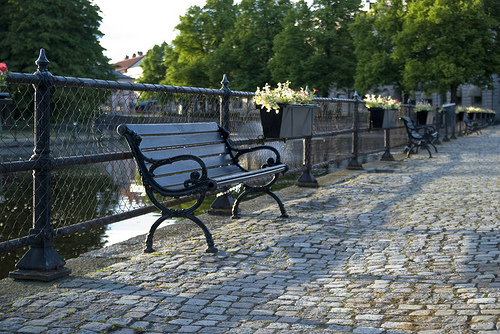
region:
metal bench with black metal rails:
[117, 120, 287, 252]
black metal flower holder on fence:
[250, 80, 318, 137]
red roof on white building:
[113, 53, 143, 70]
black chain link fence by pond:
[57, 85, 115, 212]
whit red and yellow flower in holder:
[257, 79, 317, 108]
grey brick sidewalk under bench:
[216, 212, 288, 254]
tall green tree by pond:
[401, 4, 489, 95]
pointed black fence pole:
[31, 47, 53, 266]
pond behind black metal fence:
[55, 143, 94, 235]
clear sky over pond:
[110, 3, 175, 41]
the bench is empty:
[108, 118, 286, 238]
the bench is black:
[99, 103, 294, 225]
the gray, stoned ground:
[236, 205, 368, 326]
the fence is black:
[22, 47, 117, 205]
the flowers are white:
[232, 73, 333, 130]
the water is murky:
[36, 162, 136, 249]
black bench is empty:
[119, 88, 277, 257]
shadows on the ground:
[208, 226, 356, 325]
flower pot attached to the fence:
[246, 65, 360, 162]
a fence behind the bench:
[91, 95, 423, 272]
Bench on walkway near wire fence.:
[111, 113, 291, 258]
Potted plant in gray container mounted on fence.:
[245, 75, 307, 138]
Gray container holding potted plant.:
[275, 101, 316, 137]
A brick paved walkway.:
[254, 248, 477, 331]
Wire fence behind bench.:
[56, 63, 116, 238]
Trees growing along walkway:
[360, 0, 499, 97]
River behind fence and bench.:
[56, 152, 130, 234]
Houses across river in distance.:
[110, 54, 154, 113]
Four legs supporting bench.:
[142, 190, 299, 257]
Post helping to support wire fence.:
[8, 45, 69, 283]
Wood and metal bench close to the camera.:
[113, 123, 289, 251]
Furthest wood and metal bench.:
[461, 112, 480, 134]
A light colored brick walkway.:
[4, 125, 499, 332]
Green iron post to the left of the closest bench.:
[11, 48, 73, 283]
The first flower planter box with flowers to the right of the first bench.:
[251, 79, 316, 136]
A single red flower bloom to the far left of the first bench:
[0, 60, 7, 74]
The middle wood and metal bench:
[402, 115, 439, 157]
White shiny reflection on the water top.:
[105, 192, 177, 247]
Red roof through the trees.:
[106, 56, 144, 71]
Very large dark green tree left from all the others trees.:
[0, 0, 113, 121]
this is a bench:
[132, 119, 264, 234]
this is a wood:
[146, 132, 208, 148]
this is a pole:
[27, 59, 73, 269]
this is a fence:
[61, 87, 98, 210]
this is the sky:
[114, 0, 153, 40]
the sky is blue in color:
[108, 16, 148, 37]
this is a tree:
[34, 10, 67, 42]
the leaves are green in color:
[268, 31, 298, 70]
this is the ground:
[341, 202, 421, 309]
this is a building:
[118, 55, 147, 74]